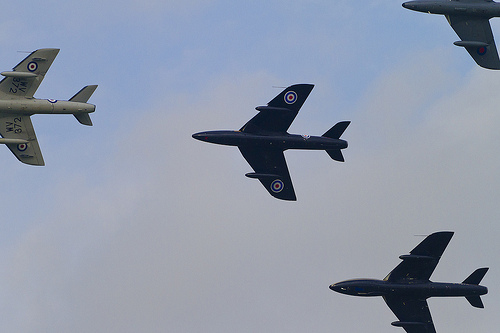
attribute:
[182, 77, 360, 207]
jet — black, gray, dark blue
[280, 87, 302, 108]
bullseye — symbol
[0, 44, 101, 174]
jet — brown, grey, light colored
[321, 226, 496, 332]
jet — black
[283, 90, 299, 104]
stickers — red, white, blue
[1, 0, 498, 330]
skies — blue, flying, gray, hazy, cloudy, slightly cloudy